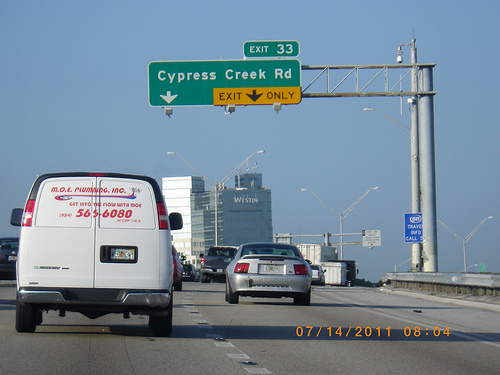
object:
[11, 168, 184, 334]
van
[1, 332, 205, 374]
street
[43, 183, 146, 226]
sign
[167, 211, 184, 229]
mirror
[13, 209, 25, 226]
mirror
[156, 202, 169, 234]
light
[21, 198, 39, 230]
light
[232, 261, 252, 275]
light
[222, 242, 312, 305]
car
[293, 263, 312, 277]
light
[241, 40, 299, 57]
sign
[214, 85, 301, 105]
sign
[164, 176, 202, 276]
building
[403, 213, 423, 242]
sign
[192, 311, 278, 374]
line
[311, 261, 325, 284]
truck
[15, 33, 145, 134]
sky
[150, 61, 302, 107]
sign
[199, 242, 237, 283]
truck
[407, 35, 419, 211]
pole